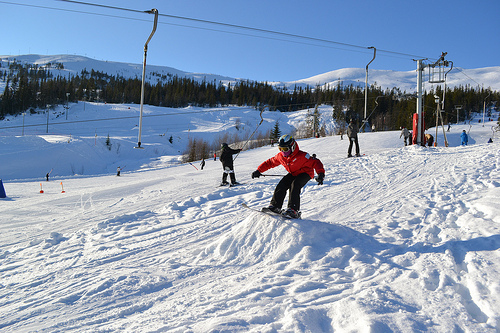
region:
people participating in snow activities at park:
[15, 11, 495, 316]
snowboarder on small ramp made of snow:
[215, 128, 367, 259]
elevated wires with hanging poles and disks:
[10, 5, 490, 150]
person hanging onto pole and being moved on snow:
[210, 95, 265, 185]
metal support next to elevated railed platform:
[410, 45, 450, 150]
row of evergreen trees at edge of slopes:
[5, 55, 495, 140]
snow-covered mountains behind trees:
[0, 45, 495, 100]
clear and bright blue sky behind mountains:
[0, 0, 495, 80]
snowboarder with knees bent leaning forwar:
[245, 130, 320, 220]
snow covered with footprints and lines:
[65, 150, 485, 325]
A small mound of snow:
[206, 208, 374, 262]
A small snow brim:
[200, 209, 373, 261]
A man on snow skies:
[254, 136, 326, 217]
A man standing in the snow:
[216, 143, 247, 186]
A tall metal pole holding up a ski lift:
[414, 60, 422, 143]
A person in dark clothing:
[344, 115, 364, 157]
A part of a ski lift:
[138, 7, 158, 147]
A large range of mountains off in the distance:
[2, 54, 497, 94]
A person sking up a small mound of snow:
[199, 134, 376, 262]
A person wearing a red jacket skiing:
[251, 133, 325, 221]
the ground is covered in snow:
[19, 252, 474, 319]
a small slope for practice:
[206, 199, 348, 265]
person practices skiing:
[239, 113, 359, 241]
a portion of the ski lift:
[132, 13, 458, 132]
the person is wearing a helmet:
[269, 129, 300, 149]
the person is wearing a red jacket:
[257, 148, 323, 180]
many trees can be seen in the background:
[3, 60, 493, 130]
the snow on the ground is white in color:
[36, 221, 339, 317]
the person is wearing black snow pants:
[269, 173, 321, 216]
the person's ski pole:
[256, 168, 287, 182]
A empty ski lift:
[132, 9, 159, 146]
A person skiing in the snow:
[250, 135, 327, 222]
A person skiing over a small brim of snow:
[251, 134, 326, 217]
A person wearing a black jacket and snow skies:
[218, 144, 245, 186]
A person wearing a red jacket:
[251, 135, 326, 220]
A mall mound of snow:
[197, 212, 364, 260]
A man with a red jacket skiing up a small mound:
[207, 134, 378, 263]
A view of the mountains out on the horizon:
[0, 54, 499, 93]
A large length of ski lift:
[0, 2, 497, 149]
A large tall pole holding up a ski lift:
[412, 54, 424, 147]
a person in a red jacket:
[240, 133, 360, 268]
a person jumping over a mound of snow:
[245, 133, 327, 258]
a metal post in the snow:
[417, 56, 424, 149]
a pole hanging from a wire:
[134, 7, 161, 152]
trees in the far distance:
[1, 61, 498, 135]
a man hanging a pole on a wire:
[339, 93, 384, 160]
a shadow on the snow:
[298, 219, 496, 271]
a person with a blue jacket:
[453, 127, 472, 147]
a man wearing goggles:
[251, 132, 326, 225]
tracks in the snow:
[350, 153, 395, 195]